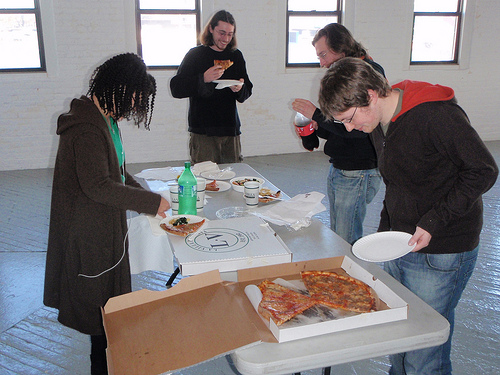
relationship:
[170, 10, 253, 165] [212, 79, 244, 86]
man holding plate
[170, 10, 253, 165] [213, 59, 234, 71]
man holding pizza slice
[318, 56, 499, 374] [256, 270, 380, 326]
man looking at a pizza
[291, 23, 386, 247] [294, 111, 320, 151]
man holding cola bottle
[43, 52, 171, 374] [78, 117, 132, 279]
woman wearing earphones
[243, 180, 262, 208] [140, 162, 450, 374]
cup on table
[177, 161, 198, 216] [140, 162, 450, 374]
bottle on table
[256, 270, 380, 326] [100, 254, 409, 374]
pizza inside a box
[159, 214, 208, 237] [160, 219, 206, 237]
plate holding pizza slice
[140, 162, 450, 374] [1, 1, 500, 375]
table inside room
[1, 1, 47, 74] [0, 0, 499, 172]
window on wall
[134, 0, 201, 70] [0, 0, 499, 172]
window on wall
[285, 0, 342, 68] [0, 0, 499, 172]
window on wall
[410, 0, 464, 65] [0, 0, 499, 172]
window on wall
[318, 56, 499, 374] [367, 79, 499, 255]
man wearing a hoodie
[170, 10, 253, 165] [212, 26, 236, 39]
man wearing glasses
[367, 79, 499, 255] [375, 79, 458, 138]
hoodie has a hood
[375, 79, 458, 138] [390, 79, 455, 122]
hood has lining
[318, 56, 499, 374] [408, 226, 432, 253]
man has a left hand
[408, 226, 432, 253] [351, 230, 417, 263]
left hand holding plate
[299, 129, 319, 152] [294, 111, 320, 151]
cola inside a cola bottle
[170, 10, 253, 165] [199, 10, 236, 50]
man has hair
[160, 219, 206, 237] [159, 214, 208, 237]
pizza slice on a plate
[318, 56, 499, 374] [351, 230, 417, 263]
man holding plate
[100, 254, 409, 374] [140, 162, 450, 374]
box on table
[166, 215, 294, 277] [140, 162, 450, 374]
box on table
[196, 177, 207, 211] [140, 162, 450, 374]
cup on table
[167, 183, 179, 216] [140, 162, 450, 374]
cup on table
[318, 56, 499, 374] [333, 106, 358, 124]
man wearing glasses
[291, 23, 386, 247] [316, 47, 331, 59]
man wearing glasses